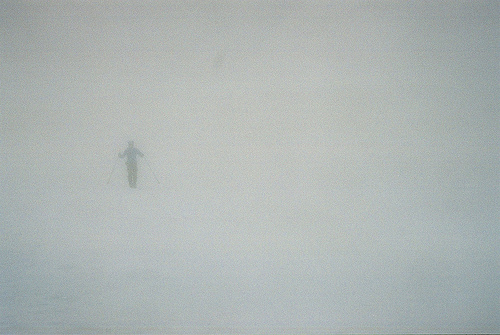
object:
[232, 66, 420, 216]
snow storm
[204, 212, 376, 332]
snow storm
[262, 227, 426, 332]
snow storm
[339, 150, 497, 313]
snow storm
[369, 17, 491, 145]
snow storm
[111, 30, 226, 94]
snow storm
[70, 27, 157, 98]
snow storm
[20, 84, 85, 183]
snow storm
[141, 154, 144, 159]
hand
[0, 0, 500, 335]
snow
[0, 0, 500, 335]
ground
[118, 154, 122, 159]
hand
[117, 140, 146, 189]
guy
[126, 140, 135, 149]
head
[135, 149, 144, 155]
arm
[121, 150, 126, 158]
arm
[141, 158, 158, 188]
stick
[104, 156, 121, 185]
stick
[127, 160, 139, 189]
legs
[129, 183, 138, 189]
shoes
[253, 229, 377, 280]
patch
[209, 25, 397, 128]
flurry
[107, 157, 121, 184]
pole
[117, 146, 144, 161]
jacket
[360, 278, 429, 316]
mist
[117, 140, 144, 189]
outfit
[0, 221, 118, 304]
mist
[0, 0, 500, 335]
scene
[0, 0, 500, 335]
picture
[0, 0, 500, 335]
image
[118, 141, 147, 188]
man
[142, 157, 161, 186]
pole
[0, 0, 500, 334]
field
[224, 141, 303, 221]
fog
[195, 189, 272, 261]
fog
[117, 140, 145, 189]
clothes